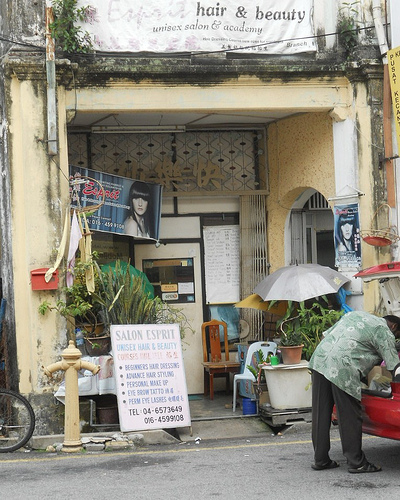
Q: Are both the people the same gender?
A: No, they are both male and female.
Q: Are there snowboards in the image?
A: No, there are no snowboards.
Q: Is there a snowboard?
A: No, there are no snowboards.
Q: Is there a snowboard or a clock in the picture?
A: No, there are no snowboards or clocks.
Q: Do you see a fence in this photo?
A: No, there are no fences.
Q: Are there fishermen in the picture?
A: No, there are no fishermen.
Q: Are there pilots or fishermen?
A: No, there are no fishermen or pilots.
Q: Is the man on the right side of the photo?
A: Yes, the man is on the right of the image.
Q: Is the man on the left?
A: No, the man is on the right of the image.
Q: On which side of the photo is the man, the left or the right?
A: The man is on the right of the image.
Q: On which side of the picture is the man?
A: The man is on the right of the image.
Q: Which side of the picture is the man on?
A: The man is on the right of the image.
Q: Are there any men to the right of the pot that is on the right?
A: Yes, there is a man to the right of the pot.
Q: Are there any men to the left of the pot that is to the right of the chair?
A: No, the man is to the right of the pot.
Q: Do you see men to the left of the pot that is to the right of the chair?
A: No, the man is to the right of the pot.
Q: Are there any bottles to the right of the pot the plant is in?
A: No, there is a man to the right of the pot.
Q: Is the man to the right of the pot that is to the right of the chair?
A: Yes, the man is to the right of the pot.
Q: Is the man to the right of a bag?
A: No, the man is to the right of the pot.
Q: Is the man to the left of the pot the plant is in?
A: No, the man is to the right of the pot.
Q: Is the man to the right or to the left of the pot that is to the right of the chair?
A: The man is to the right of the pot.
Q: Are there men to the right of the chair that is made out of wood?
A: Yes, there is a man to the right of the chair.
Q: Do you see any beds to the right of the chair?
A: No, there is a man to the right of the chair.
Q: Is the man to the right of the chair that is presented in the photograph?
A: Yes, the man is to the right of the chair.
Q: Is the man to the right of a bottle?
A: No, the man is to the right of the chair.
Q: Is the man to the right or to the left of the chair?
A: The man is to the right of the chair.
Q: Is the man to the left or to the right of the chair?
A: The man is to the right of the chair.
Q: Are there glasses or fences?
A: No, there are no fences or glasses.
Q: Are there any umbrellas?
A: Yes, there are umbrellas.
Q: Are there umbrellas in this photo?
A: Yes, there are umbrellas.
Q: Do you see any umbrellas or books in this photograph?
A: Yes, there are umbrellas.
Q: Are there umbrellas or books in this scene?
A: Yes, there are umbrellas.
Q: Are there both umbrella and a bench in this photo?
A: No, there are umbrellas but no benches.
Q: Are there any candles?
A: No, there are no candles.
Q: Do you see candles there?
A: No, there are no candles.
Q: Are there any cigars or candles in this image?
A: No, there are no candles or cigars.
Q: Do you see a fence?
A: No, there are no fences.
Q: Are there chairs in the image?
A: Yes, there is a chair.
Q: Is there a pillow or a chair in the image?
A: Yes, there is a chair.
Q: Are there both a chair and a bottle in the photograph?
A: No, there is a chair but no bottles.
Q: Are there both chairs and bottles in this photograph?
A: No, there is a chair but no bottles.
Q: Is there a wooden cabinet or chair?
A: Yes, there is a wood chair.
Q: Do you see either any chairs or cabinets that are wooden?
A: Yes, the chair is wooden.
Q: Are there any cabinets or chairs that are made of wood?
A: Yes, the chair is made of wood.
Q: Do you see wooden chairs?
A: Yes, there is a wood chair.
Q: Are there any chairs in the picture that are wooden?
A: Yes, there is a chair that is wooden.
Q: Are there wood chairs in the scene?
A: Yes, there is a chair that is made of wood.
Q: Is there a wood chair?
A: Yes, there is a chair that is made of wood.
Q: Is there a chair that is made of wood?
A: Yes, there is a chair that is made of wood.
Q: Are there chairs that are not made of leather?
A: Yes, there is a chair that is made of wood.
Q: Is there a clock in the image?
A: No, there are no clocks.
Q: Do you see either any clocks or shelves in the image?
A: No, there are no clocks or shelves.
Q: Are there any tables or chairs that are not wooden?
A: No, there is a chair but it is wooden.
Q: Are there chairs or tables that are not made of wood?
A: No, there is a chair but it is made of wood.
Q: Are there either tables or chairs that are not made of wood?
A: No, there is a chair but it is made of wood.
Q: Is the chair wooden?
A: Yes, the chair is wooden.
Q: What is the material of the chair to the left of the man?
A: The chair is made of wood.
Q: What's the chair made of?
A: The chair is made of wood.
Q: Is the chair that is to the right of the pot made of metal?
A: No, the chair is made of wood.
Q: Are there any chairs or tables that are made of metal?
A: No, there is a chair but it is made of wood.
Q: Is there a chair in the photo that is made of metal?
A: No, there is a chair but it is made of wood.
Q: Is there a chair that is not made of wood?
A: No, there is a chair but it is made of wood.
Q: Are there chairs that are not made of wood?
A: No, there is a chair but it is made of wood.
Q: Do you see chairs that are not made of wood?
A: No, there is a chair but it is made of wood.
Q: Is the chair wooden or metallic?
A: The chair is wooden.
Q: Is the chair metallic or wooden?
A: The chair is wooden.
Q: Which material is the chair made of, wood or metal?
A: The chair is made of wood.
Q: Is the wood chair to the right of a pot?
A: Yes, the chair is to the right of a pot.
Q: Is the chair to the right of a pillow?
A: No, the chair is to the right of a pot.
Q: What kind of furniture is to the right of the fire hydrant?
A: The piece of furniture is a chair.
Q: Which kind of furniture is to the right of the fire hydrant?
A: The piece of furniture is a chair.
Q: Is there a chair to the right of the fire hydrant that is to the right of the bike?
A: Yes, there is a chair to the right of the hydrant.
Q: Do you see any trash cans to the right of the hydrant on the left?
A: No, there is a chair to the right of the fire hydrant.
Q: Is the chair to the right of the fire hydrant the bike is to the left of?
A: Yes, the chair is to the right of the fire hydrant.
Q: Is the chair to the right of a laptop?
A: No, the chair is to the right of the fire hydrant.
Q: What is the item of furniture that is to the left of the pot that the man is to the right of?
A: The piece of furniture is a chair.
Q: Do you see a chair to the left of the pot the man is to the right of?
A: Yes, there is a chair to the left of the pot.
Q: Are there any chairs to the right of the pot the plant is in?
A: No, the chair is to the left of the pot.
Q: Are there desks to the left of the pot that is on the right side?
A: No, there is a chair to the left of the pot.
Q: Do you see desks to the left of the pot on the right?
A: No, there is a chair to the left of the pot.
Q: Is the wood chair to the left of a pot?
A: Yes, the chair is to the left of a pot.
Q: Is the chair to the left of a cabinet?
A: No, the chair is to the left of a pot.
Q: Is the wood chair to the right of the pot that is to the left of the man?
A: No, the chair is to the left of the pot.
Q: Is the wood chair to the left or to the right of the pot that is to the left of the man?
A: The chair is to the left of the pot.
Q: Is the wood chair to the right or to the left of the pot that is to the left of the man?
A: The chair is to the left of the pot.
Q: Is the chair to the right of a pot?
A: Yes, the chair is to the right of a pot.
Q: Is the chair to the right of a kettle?
A: No, the chair is to the right of a pot.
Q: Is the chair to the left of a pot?
A: No, the chair is to the right of a pot.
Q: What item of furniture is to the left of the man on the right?
A: The piece of furniture is a chair.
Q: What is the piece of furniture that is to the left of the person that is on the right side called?
A: The piece of furniture is a chair.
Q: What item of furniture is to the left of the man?
A: The piece of furniture is a chair.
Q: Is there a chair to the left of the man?
A: Yes, there is a chair to the left of the man.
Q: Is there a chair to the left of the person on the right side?
A: Yes, there is a chair to the left of the man.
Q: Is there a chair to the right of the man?
A: No, the chair is to the left of the man.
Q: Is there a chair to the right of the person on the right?
A: No, the chair is to the left of the man.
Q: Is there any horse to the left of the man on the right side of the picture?
A: No, there is a chair to the left of the man.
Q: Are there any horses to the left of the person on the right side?
A: No, there is a chair to the left of the man.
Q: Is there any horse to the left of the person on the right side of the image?
A: No, there is a chair to the left of the man.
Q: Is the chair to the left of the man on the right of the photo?
A: Yes, the chair is to the left of the man.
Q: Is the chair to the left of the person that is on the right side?
A: Yes, the chair is to the left of the man.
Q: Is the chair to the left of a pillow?
A: No, the chair is to the left of the man.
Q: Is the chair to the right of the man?
A: No, the chair is to the left of the man.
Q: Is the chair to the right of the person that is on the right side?
A: No, the chair is to the left of the man.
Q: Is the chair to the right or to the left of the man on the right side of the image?
A: The chair is to the left of the man.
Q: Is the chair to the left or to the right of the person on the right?
A: The chair is to the left of the man.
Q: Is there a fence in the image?
A: No, there are no fences.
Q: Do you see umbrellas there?
A: Yes, there is an umbrella.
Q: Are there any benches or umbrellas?
A: Yes, there is an umbrella.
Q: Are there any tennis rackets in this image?
A: No, there are no tennis rackets.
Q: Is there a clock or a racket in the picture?
A: No, there are no rackets or clocks.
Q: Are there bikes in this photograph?
A: Yes, there is a bike.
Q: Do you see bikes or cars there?
A: Yes, there is a bike.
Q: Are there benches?
A: No, there are no benches.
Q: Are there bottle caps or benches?
A: No, there are no benches or bottle caps.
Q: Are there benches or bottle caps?
A: No, there are no benches or bottle caps.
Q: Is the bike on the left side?
A: Yes, the bike is on the left of the image.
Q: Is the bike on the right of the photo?
A: No, the bike is on the left of the image.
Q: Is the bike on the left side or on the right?
A: The bike is on the left of the image.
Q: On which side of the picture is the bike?
A: The bike is on the left of the image.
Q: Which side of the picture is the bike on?
A: The bike is on the left of the image.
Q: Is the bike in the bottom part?
A: Yes, the bike is in the bottom of the image.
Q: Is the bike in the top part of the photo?
A: No, the bike is in the bottom of the image.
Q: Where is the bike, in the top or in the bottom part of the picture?
A: The bike is in the bottom of the image.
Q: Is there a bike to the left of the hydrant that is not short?
A: Yes, there is a bike to the left of the hydrant.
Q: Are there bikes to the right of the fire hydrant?
A: No, the bike is to the left of the fire hydrant.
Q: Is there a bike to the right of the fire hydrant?
A: No, the bike is to the left of the fire hydrant.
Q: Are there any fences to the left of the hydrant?
A: No, there is a bike to the left of the hydrant.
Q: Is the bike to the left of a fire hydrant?
A: Yes, the bike is to the left of a fire hydrant.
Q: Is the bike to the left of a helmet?
A: No, the bike is to the left of a fire hydrant.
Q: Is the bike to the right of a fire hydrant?
A: No, the bike is to the left of a fire hydrant.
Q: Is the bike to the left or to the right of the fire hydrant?
A: The bike is to the left of the fire hydrant.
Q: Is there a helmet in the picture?
A: No, there are no helmets.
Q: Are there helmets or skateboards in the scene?
A: No, there are no helmets or skateboards.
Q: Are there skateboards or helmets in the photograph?
A: No, there are no helmets or skateboards.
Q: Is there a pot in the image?
A: Yes, there is a pot.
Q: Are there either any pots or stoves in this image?
A: Yes, there is a pot.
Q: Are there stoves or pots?
A: Yes, there is a pot.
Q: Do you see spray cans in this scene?
A: No, there are no spray cans.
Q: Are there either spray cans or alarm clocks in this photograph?
A: No, there are no spray cans or alarm clocks.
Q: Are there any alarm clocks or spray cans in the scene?
A: No, there are no spray cans or alarm clocks.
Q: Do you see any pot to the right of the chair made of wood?
A: Yes, there is a pot to the right of the chair.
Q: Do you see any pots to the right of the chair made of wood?
A: Yes, there is a pot to the right of the chair.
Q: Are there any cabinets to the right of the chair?
A: No, there is a pot to the right of the chair.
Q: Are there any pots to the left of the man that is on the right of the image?
A: Yes, there is a pot to the left of the man.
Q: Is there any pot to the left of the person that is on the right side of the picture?
A: Yes, there is a pot to the left of the man.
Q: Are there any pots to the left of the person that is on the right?
A: Yes, there is a pot to the left of the man.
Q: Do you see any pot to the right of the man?
A: No, the pot is to the left of the man.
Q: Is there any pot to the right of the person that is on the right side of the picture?
A: No, the pot is to the left of the man.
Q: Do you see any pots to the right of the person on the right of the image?
A: No, the pot is to the left of the man.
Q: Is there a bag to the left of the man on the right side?
A: No, there is a pot to the left of the man.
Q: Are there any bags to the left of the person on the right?
A: No, there is a pot to the left of the man.